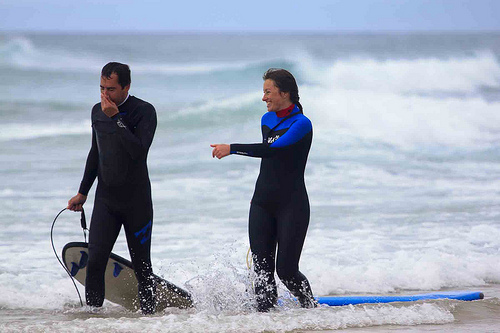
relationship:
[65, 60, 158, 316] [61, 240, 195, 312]
man pulling body board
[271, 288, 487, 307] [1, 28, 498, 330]
surfboard in water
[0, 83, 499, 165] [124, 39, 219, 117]
wave in water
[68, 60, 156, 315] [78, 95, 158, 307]
man wears wet suit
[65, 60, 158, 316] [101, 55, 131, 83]
man has hair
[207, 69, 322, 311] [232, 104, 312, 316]
person wearing wetsuit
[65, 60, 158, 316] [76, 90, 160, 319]
man wearing wetsuit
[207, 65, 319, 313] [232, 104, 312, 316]
person in wetsuit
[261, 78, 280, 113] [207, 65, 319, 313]
face of person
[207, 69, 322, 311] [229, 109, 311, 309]
person in wetsuit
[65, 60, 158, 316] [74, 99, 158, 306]
man in wetsuit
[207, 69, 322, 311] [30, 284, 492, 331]
person at beach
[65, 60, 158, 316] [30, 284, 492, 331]
man at beach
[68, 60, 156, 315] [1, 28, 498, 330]
man standing in water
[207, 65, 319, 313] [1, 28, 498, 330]
person standing in water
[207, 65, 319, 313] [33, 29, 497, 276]
person standing in water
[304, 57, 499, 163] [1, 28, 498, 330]
wave on water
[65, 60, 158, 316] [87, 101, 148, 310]
man in wetsuit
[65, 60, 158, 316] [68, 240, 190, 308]
man with body board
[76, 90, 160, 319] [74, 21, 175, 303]
wetsuit of man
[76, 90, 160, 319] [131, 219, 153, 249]
wetsuit with stripes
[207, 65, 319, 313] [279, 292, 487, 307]
person with surfboard